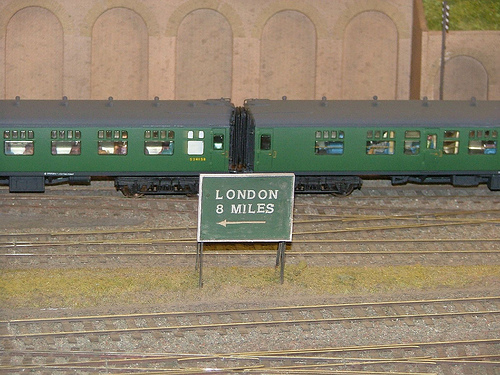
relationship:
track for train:
[7, 225, 497, 258] [0, 96, 498, 199]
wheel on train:
[122, 183, 149, 195] [0, 96, 498, 199]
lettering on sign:
[214, 190, 279, 202] [196, 173, 294, 242]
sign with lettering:
[196, 173, 294, 242] [214, 190, 279, 202]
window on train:
[141, 139, 173, 156] [0, 96, 498, 199]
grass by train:
[0, 263, 497, 301] [0, 96, 498, 199]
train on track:
[0, 96, 498, 199] [7, 225, 497, 258]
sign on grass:
[196, 173, 294, 242] [0, 263, 497, 301]